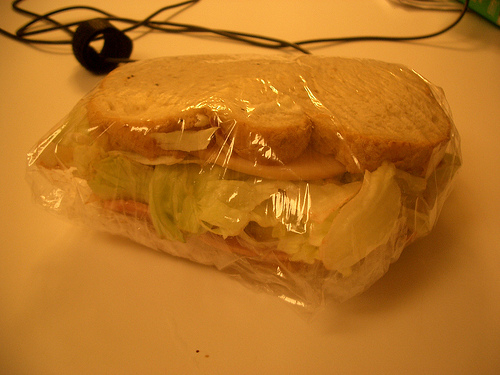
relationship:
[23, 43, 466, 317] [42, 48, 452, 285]
plastic around sandwich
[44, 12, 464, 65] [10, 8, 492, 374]
cord on table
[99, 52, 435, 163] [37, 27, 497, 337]
bread on table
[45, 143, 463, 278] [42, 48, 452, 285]
green lettuce in sandwich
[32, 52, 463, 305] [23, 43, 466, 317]
sandwhich wrapped in plastic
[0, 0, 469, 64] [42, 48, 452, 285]
cord behind sandwich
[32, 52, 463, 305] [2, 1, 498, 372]
sandwhich on surface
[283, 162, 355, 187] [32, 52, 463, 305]
ham in sandwhich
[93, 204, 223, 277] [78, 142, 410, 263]
bread under lettuce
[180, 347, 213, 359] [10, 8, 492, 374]
crumbs on table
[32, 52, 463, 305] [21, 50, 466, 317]
sandwhich in wrap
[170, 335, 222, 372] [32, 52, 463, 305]
crumbs from sandwhich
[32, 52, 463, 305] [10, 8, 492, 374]
sandwhich on table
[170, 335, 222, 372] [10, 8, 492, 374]
crumbs on table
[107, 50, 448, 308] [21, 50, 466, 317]
sandwhich in wrap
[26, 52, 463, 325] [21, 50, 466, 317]
light reflecting on wrap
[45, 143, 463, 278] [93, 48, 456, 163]
green lettuce in middle of bread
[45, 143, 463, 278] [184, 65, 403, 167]
green lettuce in middle of bread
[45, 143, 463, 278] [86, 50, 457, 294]
green lettuce in middle of bread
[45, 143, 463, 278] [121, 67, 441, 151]
green lettuce in middle of bread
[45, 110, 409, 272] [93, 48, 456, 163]
green lettuce in middle of bread